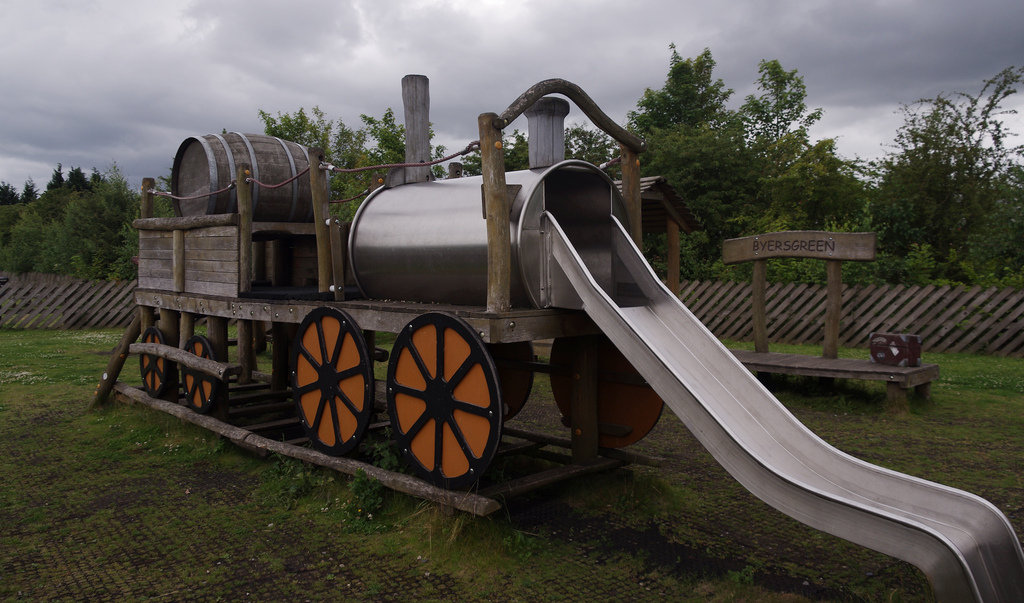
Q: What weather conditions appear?
A: It is overcast.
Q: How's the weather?
A: It is overcast.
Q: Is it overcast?
A: Yes, it is overcast.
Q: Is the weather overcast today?
A: Yes, it is overcast.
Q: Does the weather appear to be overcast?
A: Yes, it is overcast.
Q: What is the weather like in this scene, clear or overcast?
A: It is overcast.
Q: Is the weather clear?
A: No, it is overcast.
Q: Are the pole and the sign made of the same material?
A: Yes, both the pole and the sign are made of wood.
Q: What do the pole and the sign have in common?
A: The material, both the pole and the sign are wooden.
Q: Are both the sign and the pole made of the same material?
A: Yes, both the sign and the pole are made of wood.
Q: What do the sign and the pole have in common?
A: The material, both the sign and the pole are wooden.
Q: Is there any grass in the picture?
A: Yes, there is grass.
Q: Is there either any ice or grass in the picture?
A: Yes, there is grass.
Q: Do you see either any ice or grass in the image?
A: Yes, there is grass.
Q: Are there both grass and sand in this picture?
A: No, there is grass but no sand.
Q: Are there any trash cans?
A: No, there are no trash cans.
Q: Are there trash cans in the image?
A: No, there are no trash cans.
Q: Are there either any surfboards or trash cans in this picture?
A: No, there are no trash cans or surfboards.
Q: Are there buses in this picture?
A: No, there are no buses.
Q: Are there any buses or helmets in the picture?
A: No, there are no buses or helmets.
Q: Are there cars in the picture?
A: No, there are no cars.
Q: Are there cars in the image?
A: No, there are no cars.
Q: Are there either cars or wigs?
A: No, there are no cars or wigs.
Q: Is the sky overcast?
A: Yes, the sky is overcast.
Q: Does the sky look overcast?
A: Yes, the sky is overcast.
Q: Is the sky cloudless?
A: No, the sky is overcast.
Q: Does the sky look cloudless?
A: No, the sky is overcast.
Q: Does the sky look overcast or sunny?
A: The sky is overcast.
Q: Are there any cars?
A: No, there are no cars.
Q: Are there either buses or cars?
A: No, there are no cars or buses.